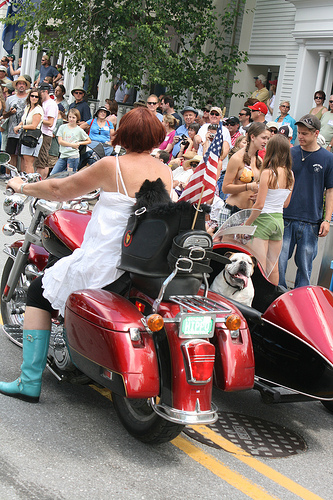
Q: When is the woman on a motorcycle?
A: Daytime.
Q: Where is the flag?
A: Back of bike.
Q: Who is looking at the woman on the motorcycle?
A: The crowd.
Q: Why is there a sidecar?
A: Passenger.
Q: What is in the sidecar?
A: Dog.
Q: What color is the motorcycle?
A: Red.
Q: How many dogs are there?
A: One.